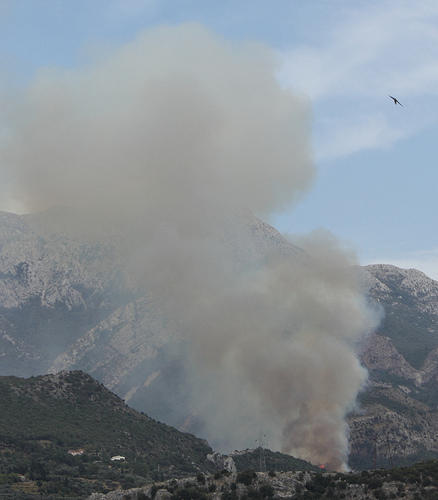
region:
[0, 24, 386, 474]
the large smoke plume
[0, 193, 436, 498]
the large area of mountains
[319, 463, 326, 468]
the flame in the smoke plume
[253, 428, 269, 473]
the tower on the mountain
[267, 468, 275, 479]
the tree on the mountain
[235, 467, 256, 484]
the tree on the mountain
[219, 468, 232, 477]
the tree on the mountain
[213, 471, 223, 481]
the tree on the mountain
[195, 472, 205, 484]
the tree on the mountain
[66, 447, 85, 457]
the building on the mountain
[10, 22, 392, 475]
volcano smoke rising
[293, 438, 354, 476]
red lava under gray smoke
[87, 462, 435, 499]
spots of green on rocky hill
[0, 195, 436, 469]
rocky mountain behind smoke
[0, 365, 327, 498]
greenish hill on left front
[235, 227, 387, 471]
brownish gray smoke close to lava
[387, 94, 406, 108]
bird flying in sky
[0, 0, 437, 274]
white clouds in blue sky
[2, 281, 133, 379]
dark patches under rocky mountain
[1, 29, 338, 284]
huge puff of smoke at top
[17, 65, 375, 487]
large cloud of smoke from fire in mountains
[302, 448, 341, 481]
orange flames of fire in the mountains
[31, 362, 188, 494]
green plants growing in dirt on hillside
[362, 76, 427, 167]
black bird flying through the blue sky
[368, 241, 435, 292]
clouds and blue skies above mountains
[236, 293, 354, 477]
brown and gray ash rising from the fire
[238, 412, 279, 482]
electrical tower on the mountain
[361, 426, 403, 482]
two wooden power poles on the hill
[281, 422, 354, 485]
ash and smoke coming from the flames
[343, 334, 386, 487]
edge of smoke cloud from fire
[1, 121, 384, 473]
grey smoke billowing in the sky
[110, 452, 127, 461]
a rock on the ground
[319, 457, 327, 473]
an orange flame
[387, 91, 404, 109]
a bird flying in the sky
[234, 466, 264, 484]
a green bush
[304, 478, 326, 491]
a small green bush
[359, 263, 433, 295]
the peak of a mountain in the distance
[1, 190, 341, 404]
view of mountain obscured by smoke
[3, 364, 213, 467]
hill covered in vegetation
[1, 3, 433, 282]
sky filled with smoke and clouds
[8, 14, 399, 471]
A large cloud of smoke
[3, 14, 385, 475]
The cloud of smoke is gray in color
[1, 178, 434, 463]
Mountains in the background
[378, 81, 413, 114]
A bird is flying in the air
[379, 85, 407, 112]
The bird is in shadow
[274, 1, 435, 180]
A light colored cloud in the sky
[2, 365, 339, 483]
Plants and small trees are covering the mountain top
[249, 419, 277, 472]
An electric tower in the foreground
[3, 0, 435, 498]
Photo was taken in the daytime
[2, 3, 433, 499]
Photo was taken outdoors